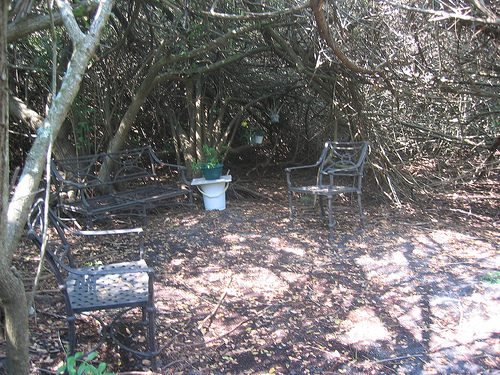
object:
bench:
[284, 141, 372, 241]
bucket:
[201, 183, 228, 211]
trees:
[89, 2, 129, 65]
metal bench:
[46, 145, 196, 243]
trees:
[160, 48, 256, 130]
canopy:
[0, 0, 500, 255]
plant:
[187, 144, 228, 172]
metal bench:
[21, 197, 158, 374]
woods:
[64, 32, 444, 332]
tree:
[213, 84, 310, 180]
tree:
[395, 6, 498, 113]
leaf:
[36, 124, 51, 138]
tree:
[0, 0, 116, 374]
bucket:
[254, 135, 264, 144]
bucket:
[200, 164, 224, 180]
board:
[191, 174, 232, 185]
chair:
[22, 193, 159, 372]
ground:
[2, 173, 498, 373]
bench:
[47, 145, 196, 243]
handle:
[196, 182, 230, 198]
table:
[191, 175, 232, 186]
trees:
[296, 82, 373, 138]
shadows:
[150, 210, 450, 372]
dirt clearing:
[68, 189, 498, 370]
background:
[3, 3, 499, 206]